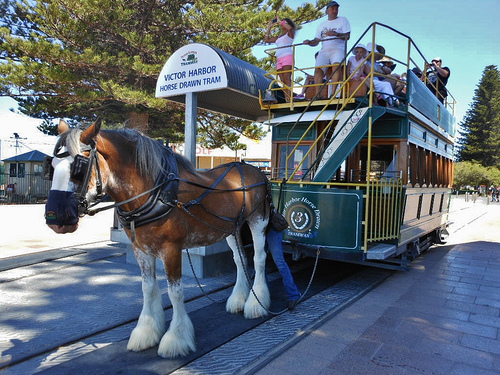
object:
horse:
[47, 116, 271, 359]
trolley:
[265, 35, 455, 258]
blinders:
[71, 154, 94, 182]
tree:
[1, 1, 278, 145]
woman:
[263, 16, 297, 108]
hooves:
[129, 297, 190, 356]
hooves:
[226, 272, 271, 317]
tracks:
[16, 256, 361, 374]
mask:
[43, 190, 81, 225]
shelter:
[155, 43, 271, 123]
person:
[241, 169, 301, 309]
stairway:
[295, 84, 369, 183]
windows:
[359, 144, 456, 186]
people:
[262, 1, 458, 112]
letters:
[156, 65, 220, 95]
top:
[268, 48, 456, 135]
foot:
[155, 320, 197, 357]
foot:
[126, 316, 164, 351]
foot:
[222, 284, 247, 315]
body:
[155, 161, 255, 246]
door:
[359, 177, 405, 251]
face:
[46, 133, 91, 228]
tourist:
[309, 0, 349, 110]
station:
[150, 40, 275, 177]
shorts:
[274, 55, 291, 71]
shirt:
[427, 69, 449, 94]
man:
[420, 57, 448, 105]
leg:
[266, 229, 302, 308]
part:
[4, 164, 41, 194]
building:
[3, 148, 50, 201]